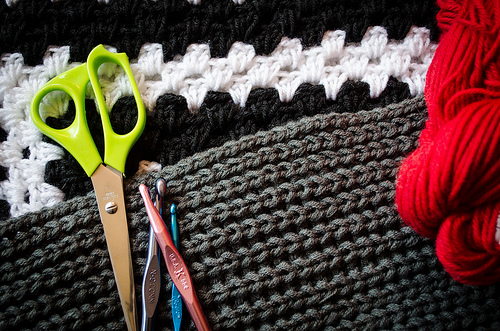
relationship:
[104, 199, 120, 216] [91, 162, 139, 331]
screw holds blades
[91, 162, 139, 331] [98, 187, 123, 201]
blades have writing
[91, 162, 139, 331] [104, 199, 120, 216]
blades have screw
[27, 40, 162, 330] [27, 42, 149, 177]
scissors has handle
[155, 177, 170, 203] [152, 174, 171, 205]
end has ball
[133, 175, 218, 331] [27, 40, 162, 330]
needles are next to scissors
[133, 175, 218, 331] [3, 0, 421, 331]
needles are on blanket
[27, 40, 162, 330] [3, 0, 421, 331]
scissors are on blanket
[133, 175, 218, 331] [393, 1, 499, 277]
needles near yarn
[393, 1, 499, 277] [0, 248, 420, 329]
red yarn on gray yarn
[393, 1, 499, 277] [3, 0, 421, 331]
yarn on blanket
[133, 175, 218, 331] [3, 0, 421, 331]
needles are for crochet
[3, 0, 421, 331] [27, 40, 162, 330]
blanket under scissors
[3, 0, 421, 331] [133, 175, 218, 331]
blanket under needles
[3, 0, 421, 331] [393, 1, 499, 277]
blanket under yarn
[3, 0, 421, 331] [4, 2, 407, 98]
blanket over crochet work